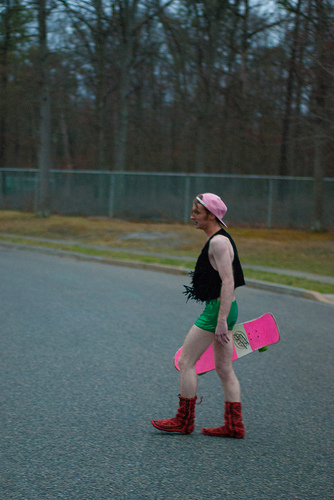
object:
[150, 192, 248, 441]
man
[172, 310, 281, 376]
skateboard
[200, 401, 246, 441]
shoes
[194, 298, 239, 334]
shorts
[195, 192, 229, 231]
ball cap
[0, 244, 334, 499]
road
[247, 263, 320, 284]
sidewalk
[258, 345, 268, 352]
wheels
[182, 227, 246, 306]
vest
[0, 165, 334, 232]
fence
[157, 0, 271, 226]
trees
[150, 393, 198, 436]
boots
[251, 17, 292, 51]
branches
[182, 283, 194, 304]
tassels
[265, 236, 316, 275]
grass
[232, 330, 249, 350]
design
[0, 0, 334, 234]
background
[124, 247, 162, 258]
part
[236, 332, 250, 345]
line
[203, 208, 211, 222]
sideburns